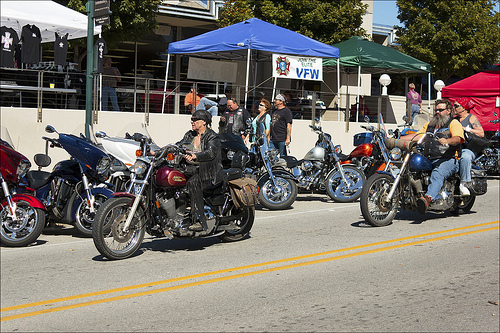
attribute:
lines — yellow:
[1, 217, 498, 324]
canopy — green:
[324, 33, 433, 76]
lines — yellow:
[86, 288, 108, 307]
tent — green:
[340, 21, 444, 142]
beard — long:
[429, 113, 454, 128]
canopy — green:
[330, 23, 442, 112]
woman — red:
[453, 95, 486, 202]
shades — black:
[260, 103, 267, 108]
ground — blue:
[374, 145, 430, 185]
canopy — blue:
[158, 16, 344, 115]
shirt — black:
[51, 33, 67, 63]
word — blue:
[299, 60, 314, 69]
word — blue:
[293, 56, 306, 63]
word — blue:
[305, 57, 316, 63]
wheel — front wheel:
[93, 195, 146, 265]